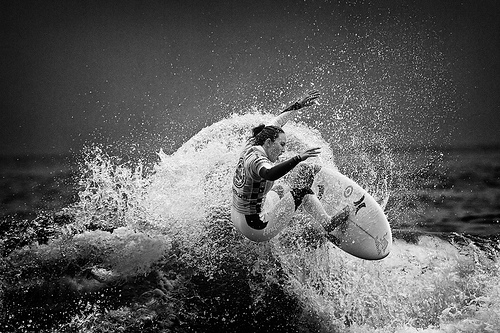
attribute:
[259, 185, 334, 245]
pants — white